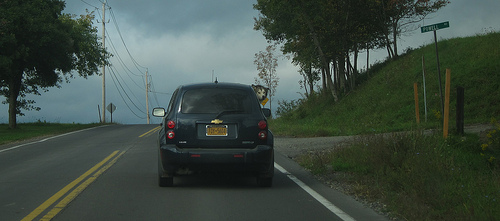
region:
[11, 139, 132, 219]
solid double yellow lines in middle of the road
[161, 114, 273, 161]
car's back taillights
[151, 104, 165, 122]
driver's side rearview mirrow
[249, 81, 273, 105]
dog's head outside car window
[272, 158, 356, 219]
solid white line on right side of road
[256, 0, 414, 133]
trees on the grassy slope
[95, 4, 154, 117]
utility lines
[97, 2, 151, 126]
utility line poles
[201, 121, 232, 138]
license plate on back of car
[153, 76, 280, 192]
dark suv on right side of the road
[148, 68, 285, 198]
a dark car is on the road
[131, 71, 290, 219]
the car is going uphill on the street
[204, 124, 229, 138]
the license tag is on the car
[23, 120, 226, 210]
a double line is in the middle of the road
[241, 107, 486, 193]
a side road is next to the car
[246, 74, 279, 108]
a doggie is hanging out of the car's rear window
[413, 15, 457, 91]
a directional sign is on the side road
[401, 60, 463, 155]
snow sticks are on the side road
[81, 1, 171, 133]
telephone poles are on the side of the road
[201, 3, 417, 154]
trees are growing on the hillside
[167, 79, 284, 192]
black car traveling north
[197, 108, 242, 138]
yellow license tag on back of car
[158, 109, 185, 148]
red lights on the car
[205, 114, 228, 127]
make of the car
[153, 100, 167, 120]
side view mirror on the car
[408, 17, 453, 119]
street sign on the ground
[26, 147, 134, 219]
yellow markings on the road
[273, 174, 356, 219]
white mark on the side of road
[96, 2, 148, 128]
telephone wires between poles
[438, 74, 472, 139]
posts on the side of road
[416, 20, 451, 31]
a green street sign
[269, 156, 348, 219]
a long white line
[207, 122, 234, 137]
a yellow license plate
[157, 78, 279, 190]
a small car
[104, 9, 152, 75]
a long electrical power line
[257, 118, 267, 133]
a red taillight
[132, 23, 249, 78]
part of a white cloud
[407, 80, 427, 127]
a long yellow pole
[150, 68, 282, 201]
The rear of a moving vehicle on a road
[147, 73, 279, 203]
The rear of a moving vehicle on a road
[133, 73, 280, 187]
the back of a car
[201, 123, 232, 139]
yellow license plate on a car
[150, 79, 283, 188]
dark colored car on the road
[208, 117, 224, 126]
chevrolet logo on a car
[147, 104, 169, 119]
rear view mirror on the car's driver side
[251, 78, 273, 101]
dog hanging out the car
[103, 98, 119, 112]
back of a diamond shaped sign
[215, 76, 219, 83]
antennae on a car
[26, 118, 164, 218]
yellow double line on the road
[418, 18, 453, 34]
green street sign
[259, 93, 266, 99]
nose of a dog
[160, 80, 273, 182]
A car on a road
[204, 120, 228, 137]
A yellow license plate on a car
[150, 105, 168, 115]
A side mirror on a car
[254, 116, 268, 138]
Tail lights on a car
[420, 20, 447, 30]
A green street sign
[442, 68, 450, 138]
A wooden post near a road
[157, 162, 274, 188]
Rear tires on a car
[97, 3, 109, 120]
A tall pole with electrical lines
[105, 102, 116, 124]
A sign near a road